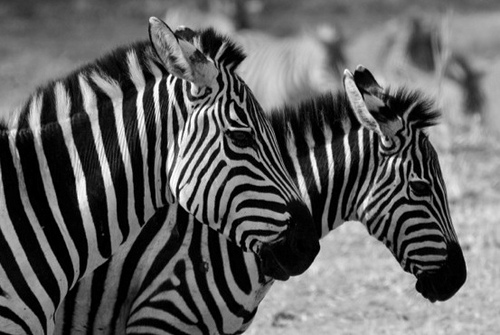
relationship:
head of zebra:
[133, 14, 331, 283] [1, 12, 328, 333]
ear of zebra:
[146, 13, 220, 93] [1, 12, 328, 333]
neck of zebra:
[33, 91, 181, 262] [1, 12, 328, 333]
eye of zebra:
[226, 126, 254, 149] [1, 12, 328, 333]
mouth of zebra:
[261, 240, 297, 278] [1, 12, 328, 333]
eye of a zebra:
[226, 126, 254, 149] [1, 12, 328, 333]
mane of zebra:
[15, 25, 251, 125] [1, 12, 328, 333]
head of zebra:
[303, 59, 479, 284] [1, 12, 328, 333]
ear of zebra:
[146, 13, 220, 93] [125, 26, 323, 273]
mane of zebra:
[15, 25, 251, 125] [21, 46, 321, 309]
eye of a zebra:
[226, 126, 254, 149] [70, 25, 328, 319]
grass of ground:
[242, 66, 499, 331] [310, 285, 391, 326]